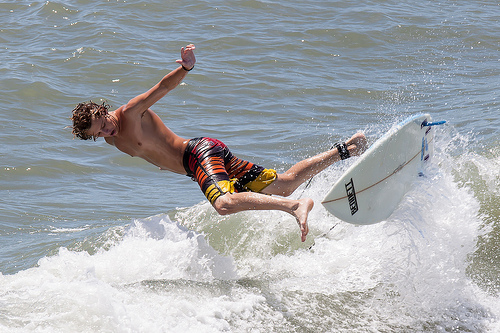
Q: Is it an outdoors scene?
A: Yes, it is outdoors.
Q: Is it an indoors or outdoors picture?
A: It is outdoors.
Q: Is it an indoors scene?
A: No, it is outdoors.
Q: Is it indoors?
A: No, it is outdoors.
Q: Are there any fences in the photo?
A: No, there are no fences.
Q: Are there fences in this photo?
A: No, there are no fences.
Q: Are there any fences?
A: No, there are no fences.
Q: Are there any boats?
A: No, there are no boats.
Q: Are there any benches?
A: No, there are no benches.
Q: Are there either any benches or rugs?
A: No, there are no benches or rugs.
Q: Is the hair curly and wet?
A: Yes, the hair is curly and wet.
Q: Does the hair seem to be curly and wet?
A: Yes, the hair is curly and wet.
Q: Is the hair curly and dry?
A: No, the hair is curly but wet.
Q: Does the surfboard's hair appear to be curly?
A: Yes, the hair is curly.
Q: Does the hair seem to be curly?
A: Yes, the hair is curly.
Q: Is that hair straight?
A: No, the hair is curly.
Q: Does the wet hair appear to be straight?
A: No, the hair is curly.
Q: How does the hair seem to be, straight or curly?
A: The hair is curly.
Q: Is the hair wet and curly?
A: Yes, the hair is wet and curly.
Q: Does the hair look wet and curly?
A: Yes, the hair is wet and curly.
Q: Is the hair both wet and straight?
A: No, the hair is wet but curly.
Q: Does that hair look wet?
A: Yes, the hair is wet.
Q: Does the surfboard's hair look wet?
A: Yes, the hair is wet.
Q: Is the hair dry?
A: No, the hair is wet.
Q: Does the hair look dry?
A: No, the hair is wet.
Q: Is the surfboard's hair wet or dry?
A: The hair is wet.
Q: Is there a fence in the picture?
A: No, there are no fences.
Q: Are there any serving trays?
A: No, there are no serving trays.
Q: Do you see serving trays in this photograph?
A: No, there are no serving trays.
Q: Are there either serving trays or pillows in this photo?
A: No, there are no serving trays or pillows.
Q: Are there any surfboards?
A: Yes, there is a surfboard.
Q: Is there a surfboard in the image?
A: Yes, there is a surfboard.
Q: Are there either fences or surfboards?
A: Yes, there is a surfboard.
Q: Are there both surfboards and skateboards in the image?
A: No, there is a surfboard but no skateboards.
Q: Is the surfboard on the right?
A: Yes, the surfboard is on the right of the image.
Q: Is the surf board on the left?
A: No, the surf board is on the right of the image.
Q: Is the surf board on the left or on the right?
A: The surf board is on the right of the image.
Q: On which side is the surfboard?
A: The surfboard is on the right of the image.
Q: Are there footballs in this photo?
A: No, there are no footballs.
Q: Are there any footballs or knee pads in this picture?
A: No, there are no footballs or knee pads.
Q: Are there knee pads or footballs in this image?
A: No, there are no footballs or knee pads.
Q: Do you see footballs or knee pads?
A: No, there are no footballs or knee pads.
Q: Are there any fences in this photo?
A: No, there are no fences.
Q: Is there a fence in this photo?
A: No, there are no fences.